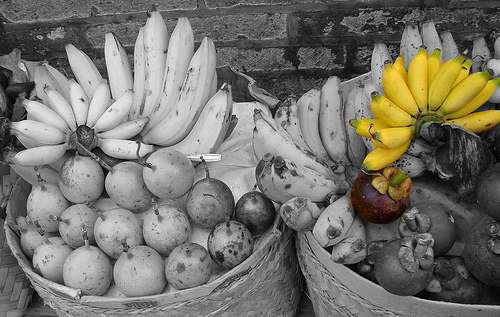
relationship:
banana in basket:
[315, 45, 487, 185] [10, 138, 302, 314]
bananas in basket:
[364, 147, 404, 169] [5, 178, 303, 315]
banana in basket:
[347, 110, 423, 177] [5, 178, 303, 315]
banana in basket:
[348, 112, 388, 139] [5, 178, 303, 315]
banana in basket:
[441, 108, 498, 130] [5, 178, 303, 315]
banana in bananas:
[379, 55, 419, 117] [364, 147, 404, 169]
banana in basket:
[315, 45, 487, 185] [275, 42, 483, 314]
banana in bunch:
[315, 45, 487, 185] [344, 39, 479, 173]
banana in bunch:
[347, 110, 423, 177] [282, 64, 480, 233]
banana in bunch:
[315, 45, 487, 185] [339, 38, 483, 197]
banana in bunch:
[379, 55, 419, 117] [348, 47, 498, 172]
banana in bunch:
[347, 110, 423, 177] [348, 47, 498, 172]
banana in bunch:
[423, 51, 464, 116] [347, 29, 484, 205]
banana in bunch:
[423, 51, 464, 116] [339, 25, 479, 161]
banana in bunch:
[405, 43, 430, 117] [353, 42, 495, 183]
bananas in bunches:
[364, 38, 493, 147] [19, 47, 491, 260]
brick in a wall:
[0, 0, 96, 25] [4, 1, 499, 171]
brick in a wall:
[243, 50, 345, 68] [5, 2, 496, 27]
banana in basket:
[405, 43, 430, 117] [282, 43, 499, 314]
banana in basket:
[438, 61, 493, 113] [282, 43, 499, 314]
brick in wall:
[85, 9, 290, 50] [214, 7, 294, 50]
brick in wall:
[85, 9, 290, 50] [221, 5, 308, 46]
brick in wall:
[125, 3, 202, 17] [226, 16, 300, 52]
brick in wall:
[0, 0, 96, 25] [196, 3, 320, 80]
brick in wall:
[346, 42, 393, 64] [8, 5, 495, 87]